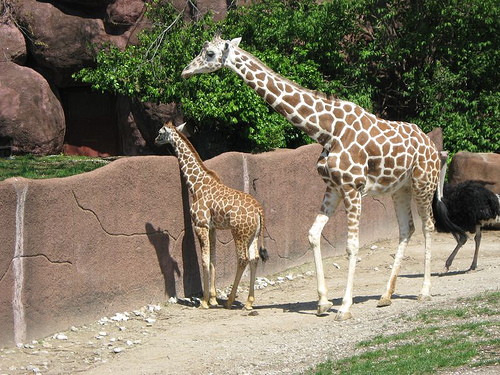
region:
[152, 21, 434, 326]
Two giraffe are shown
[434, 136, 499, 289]
There is one ostrich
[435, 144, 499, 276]
The ostrich is white and black feathers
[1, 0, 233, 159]
The rocks form an opening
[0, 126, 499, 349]
Man made rock wall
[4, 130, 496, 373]
The animals are in an enclosure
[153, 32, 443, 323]
The animals have brown spots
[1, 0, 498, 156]
The trees are green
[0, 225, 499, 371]
animals are on gravel and dirt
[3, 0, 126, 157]
Rocks are reddish brown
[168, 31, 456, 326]
Big giraffe on a zoo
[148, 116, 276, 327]
Baby giraffe near mom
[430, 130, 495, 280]
Rhea behind a giraffe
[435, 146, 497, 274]
Rhea has white neck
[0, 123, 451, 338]
Pen of giraffe is fenced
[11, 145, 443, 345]
Fence is made of cement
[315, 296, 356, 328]
Front hooves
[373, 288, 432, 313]
Back hooves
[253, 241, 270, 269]
Tail tuft is brown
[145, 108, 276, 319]
Giraffe facing to the left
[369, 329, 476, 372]
A patch of green grass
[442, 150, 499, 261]
An ostrich standing upright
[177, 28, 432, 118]
An adult ostrich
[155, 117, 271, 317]
A baby ostrich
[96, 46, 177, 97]
A leafy green tree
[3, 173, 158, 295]
A red rock wall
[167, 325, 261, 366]
A portion of a dirt path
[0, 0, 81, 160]
A portion of a rock wall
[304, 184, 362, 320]
The front legs of an adult giraffe.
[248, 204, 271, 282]
The tail of a baby giraffe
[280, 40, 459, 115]
the trees are green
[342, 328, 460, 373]
the grees are green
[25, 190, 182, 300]
the wall is brown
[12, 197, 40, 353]
the stain is white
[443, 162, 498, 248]
the ostrich is black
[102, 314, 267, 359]
the ground is rocky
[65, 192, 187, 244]
there is a crack on the wall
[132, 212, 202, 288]
there is shadow on the wall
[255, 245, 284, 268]
the tail end is black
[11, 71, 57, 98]
the rocks are grey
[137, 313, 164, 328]
small white stone on ground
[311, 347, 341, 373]
single green blade of grass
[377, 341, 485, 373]
sparse green grass cluster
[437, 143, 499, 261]
black and white bird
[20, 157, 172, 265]
large crack in brown stone wall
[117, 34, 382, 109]
large cluster of green trees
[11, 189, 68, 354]
long line in wall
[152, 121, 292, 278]
small brown and white giraffe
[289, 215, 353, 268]
white spot on long leg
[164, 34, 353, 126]
giraffe looking over wall